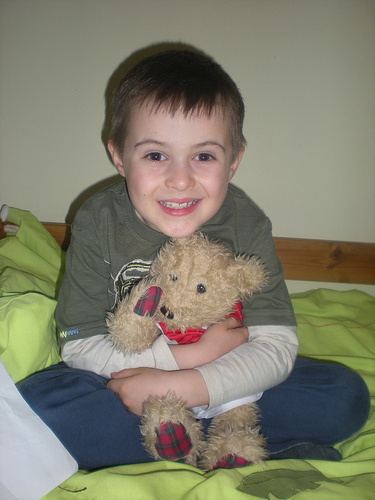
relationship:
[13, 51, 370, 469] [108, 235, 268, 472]
boy holding teddy bear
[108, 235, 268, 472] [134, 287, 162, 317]
teddy bear has plaid paw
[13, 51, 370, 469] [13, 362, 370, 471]
boy wearing jeans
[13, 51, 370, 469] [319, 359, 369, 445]
boy has knee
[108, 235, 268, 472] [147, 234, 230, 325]
teddy bear has face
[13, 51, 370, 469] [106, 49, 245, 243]
boy has head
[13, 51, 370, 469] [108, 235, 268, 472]
boy carrying teddy bear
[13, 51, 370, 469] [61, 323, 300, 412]
boy wearing long sleeved shirt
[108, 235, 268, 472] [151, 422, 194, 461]
teddy bear has red plaid foot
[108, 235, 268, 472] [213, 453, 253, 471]
teddy bear has red plaid foot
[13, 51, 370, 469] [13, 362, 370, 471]
boy wearing blue pants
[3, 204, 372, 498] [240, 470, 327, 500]
sheets have green leaf pattern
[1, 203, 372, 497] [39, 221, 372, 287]
bed has wood headboard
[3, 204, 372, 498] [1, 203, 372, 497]
sheets on top of bed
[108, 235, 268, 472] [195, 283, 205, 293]
teddy bear has eye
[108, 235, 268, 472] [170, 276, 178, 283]
teddy bear has eye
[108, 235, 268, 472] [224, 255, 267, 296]
teddy bear has ear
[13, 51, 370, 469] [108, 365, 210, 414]
boy has hand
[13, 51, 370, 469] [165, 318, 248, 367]
boy has hand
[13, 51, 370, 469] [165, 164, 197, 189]
boy has nose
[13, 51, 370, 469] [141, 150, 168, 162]
boy has eye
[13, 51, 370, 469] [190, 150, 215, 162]
boy has eye